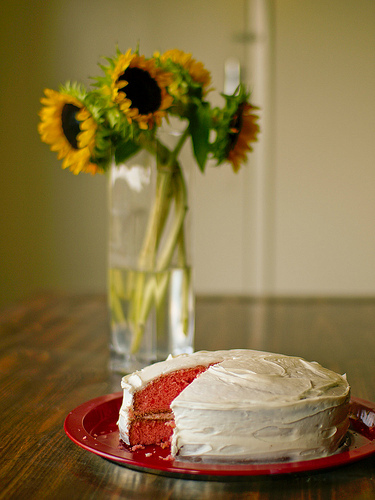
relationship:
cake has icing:
[118, 349, 352, 464] [118, 349, 351, 462]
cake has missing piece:
[118, 349, 352, 464] [132, 362, 218, 461]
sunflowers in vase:
[34, 46, 260, 358] [106, 130, 201, 375]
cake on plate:
[118, 349, 352, 464] [63, 392, 374, 479]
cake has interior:
[118, 349, 352, 464] [131, 362, 220, 458]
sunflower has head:
[110, 48, 193, 357] [98, 47, 175, 132]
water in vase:
[103, 256, 197, 366] [106, 130, 201, 375]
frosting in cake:
[140, 412, 175, 423] [118, 349, 352, 464]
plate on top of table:
[63, 392, 374, 479] [2, 290, 374, 500]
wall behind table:
[0, 0, 373, 299] [2, 290, 374, 500]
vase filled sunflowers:
[106, 130, 201, 375] [34, 46, 260, 358]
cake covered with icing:
[118, 349, 352, 464] [118, 349, 351, 462]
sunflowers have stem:
[34, 46, 260, 358] [123, 130, 196, 355]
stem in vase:
[123, 130, 196, 355] [106, 130, 201, 375]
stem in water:
[123, 130, 196, 355] [103, 256, 197, 366]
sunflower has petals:
[36, 79, 109, 177] [34, 86, 96, 175]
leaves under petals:
[64, 83, 137, 171] [34, 86, 96, 175]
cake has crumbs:
[118, 349, 352, 464] [76, 427, 171, 465]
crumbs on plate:
[76, 427, 171, 465] [63, 392, 374, 479]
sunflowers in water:
[34, 46, 260, 358] [103, 256, 197, 366]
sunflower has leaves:
[36, 79, 109, 177] [64, 83, 137, 171]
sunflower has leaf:
[110, 48, 193, 357] [186, 97, 213, 172]